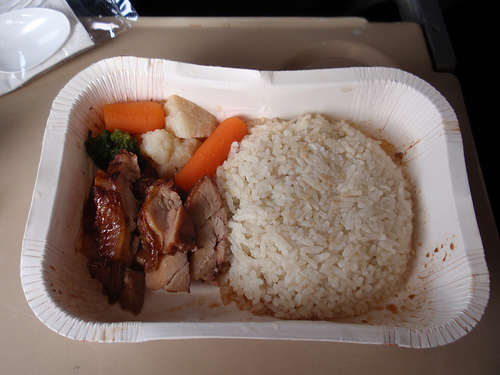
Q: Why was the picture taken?
A: To capture the food.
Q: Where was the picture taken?
A: At a table.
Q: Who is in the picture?
A: No one.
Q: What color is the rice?
A: White.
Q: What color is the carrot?
A: Orange.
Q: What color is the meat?
A: Brown.